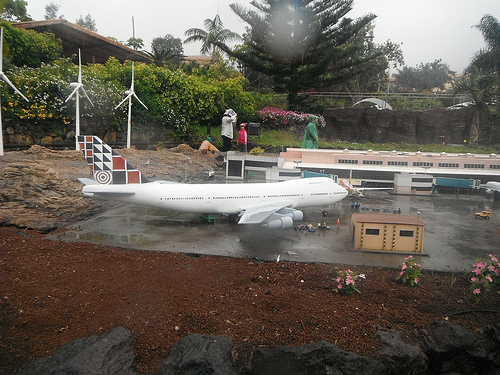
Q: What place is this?
A: It is an airport.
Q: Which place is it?
A: It is an airport.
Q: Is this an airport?
A: Yes, it is an airport.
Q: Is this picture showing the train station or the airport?
A: It is showing the airport.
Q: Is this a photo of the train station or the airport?
A: It is showing the airport.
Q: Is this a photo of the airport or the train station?
A: It is showing the airport.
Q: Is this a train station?
A: No, it is an airport.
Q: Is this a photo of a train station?
A: No, the picture is showing an airport.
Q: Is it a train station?
A: No, it is an airport.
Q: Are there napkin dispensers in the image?
A: No, there are no napkin dispensers.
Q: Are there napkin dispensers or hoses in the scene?
A: No, there are no napkin dispensers or hoses.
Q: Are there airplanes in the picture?
A: Yes, there is an airplane.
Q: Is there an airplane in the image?
A: Yes, there is an airplane.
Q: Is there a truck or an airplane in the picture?
A: Yes, there is an airplane.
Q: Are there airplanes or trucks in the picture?
A: Yes, there is an airplane.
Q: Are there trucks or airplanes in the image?
A: Yes, there is an airplane.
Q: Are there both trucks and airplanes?
A: No, there is an airplane but no trucks.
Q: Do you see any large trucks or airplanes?
A: Yes, there is a large airplane.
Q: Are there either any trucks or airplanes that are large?
A: Yes, the airplane is large.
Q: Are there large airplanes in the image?
A: Yes, there is a large airplane.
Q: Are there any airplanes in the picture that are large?
A: Yes, there is an airplane that is large.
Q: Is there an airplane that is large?
A: Yes, there is an airplane that is large.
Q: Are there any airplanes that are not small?
A: Yes, there is a large airplane.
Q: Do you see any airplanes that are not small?
A: Yes, there is a large airplane.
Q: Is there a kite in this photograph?
A: No, there are no kites.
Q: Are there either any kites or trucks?
A: No, there are no kites or trucks.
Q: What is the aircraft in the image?
A: The aircraft is an airplane.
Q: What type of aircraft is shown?
A: The aircraft is an airplane.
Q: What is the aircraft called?
A: The aircraft is an airplane.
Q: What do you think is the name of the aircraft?
A: The aircraft is an airplane.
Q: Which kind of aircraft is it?
A: The aircraft is an airplane.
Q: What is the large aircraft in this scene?
A: The aircraft is an airplane.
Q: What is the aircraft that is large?
A: The aircraft is an airplane.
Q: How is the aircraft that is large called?
A: The aircraft is an airplane.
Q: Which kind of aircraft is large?
A: The aircraft is an airplane.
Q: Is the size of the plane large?
A: Yes, the plane is large.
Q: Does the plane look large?
A: Yes, the plane is large.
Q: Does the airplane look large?
A: Yes, the airplane is large.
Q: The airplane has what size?
A: The airplane is large.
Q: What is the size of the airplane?
A: The airplane is large.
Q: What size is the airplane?
A: The airplane is large.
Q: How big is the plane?
A: The plane is large.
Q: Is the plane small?
A: No, the plane is large.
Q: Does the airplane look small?
A: No, the airplane is large.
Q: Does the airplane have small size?
A: No, the airplane is large.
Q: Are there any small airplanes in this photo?
A: No, there is an airplane but it is large.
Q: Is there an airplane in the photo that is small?
A: No, there is an airplane but it is large.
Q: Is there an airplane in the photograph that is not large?
A: No, there is an airplane but it is large.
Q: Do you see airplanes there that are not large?
A: No, there is an airplane but it is large.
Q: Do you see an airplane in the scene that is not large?
A: No, there is an airplane but it is large.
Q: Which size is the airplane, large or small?
A: The airplane is large.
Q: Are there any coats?
A: Yes, there is a coat.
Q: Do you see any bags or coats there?
A: Yes, there is a coat.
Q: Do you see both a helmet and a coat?
A: No, there is a coat but no helmets.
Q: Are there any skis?
A: No, there are no skis.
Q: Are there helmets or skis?
A: No, there are no skis or helmets.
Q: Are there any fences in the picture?
A: No, there are no fences.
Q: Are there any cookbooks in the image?
A: No, there are no cookbooks.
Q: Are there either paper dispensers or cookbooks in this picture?
A: No, there are no cookbooks or paper dispensers.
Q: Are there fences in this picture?
A: No, there are no fences.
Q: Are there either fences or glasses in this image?
A: No, there are no fences or glasses.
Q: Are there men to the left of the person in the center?
A: Yes, there is a man to the left of the person.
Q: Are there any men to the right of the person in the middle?
A: No, the man is to the left of the person.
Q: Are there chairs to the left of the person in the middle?
A: No, there is a man to the left of the person.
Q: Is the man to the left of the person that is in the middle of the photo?
A: Yes, the man is to the left of the person.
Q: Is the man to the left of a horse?
A: No, the man is to the left of the person.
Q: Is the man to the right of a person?
A: No, the man is to the left of a person.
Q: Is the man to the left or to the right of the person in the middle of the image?
A: The man is to the left of the person.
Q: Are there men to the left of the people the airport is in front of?
A: Yes, there is a man to the left of the people.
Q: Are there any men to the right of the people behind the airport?
A: No, the man is to the left of the people.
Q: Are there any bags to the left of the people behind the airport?
A: No, there is a man to the left of the people.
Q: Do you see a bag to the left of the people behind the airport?
A: No, there is a man to the left of the people.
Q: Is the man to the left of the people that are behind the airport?
A: Yes, the man is to the left of the people.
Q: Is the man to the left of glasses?
A: No, the man is to the left of the people.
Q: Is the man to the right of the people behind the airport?
A: No, the man is to the left of the people.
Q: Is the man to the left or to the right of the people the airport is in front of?
A: The man is to the left of the people.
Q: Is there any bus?
A: No, there are no buses.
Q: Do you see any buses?
A: No, there are no buses.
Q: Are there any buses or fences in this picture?
A: No, there are no buses or fences.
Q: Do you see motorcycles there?
A: No, there are no motorcycles.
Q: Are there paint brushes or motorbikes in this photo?
A: No, there are no motorbikes or paint brushes.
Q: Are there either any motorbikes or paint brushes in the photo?
A: No, there are no motorbikes or paint brushes.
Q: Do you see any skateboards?
A: No, there are no skateboards.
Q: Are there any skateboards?
A: No, there are no skateboards.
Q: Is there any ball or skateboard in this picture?
A: No, there are no skateboards or balls.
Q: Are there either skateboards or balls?
A: No, there are no skateboards or balls.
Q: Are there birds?
A: No, there are no birds.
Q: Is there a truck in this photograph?
A: No, there are no trucks.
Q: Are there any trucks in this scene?
A: No, there are no trucks.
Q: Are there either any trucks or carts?
A: No, there are no trucks or carts.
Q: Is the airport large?
A: Yes, the airport is large.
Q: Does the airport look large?
A: Yes, the airport is large.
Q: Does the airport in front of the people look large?
A: Yes, the airport is large.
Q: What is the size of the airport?
A: The airport is large.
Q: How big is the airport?
A: The airport is large.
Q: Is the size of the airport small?
A: No, the airport is large.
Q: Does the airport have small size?
A: No, the airport is large.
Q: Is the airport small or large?
A: The airport is large.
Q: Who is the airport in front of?
A: The airport is in front of the people.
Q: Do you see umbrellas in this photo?
A: No, there are no umbrellas.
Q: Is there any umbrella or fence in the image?
A: No, there are no umbrellas or fences.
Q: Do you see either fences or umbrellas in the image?
A: No, there are no umbrellas or fences.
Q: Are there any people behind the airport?
A: Yes, there are people behind the airport.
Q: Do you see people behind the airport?
A: Yes, there are people behind the airport.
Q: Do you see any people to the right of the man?
A: Yes, there are people to the right of the man.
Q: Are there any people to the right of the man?
A: Yes, there are people to the right of the man.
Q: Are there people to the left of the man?
A: No, the people are to the right of the man.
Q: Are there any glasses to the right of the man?
A: No, there are people to the right of the man.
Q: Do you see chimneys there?
A: No, there are no chimneys.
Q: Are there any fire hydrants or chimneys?
A: No, there are no chimneys or fire hydrants.